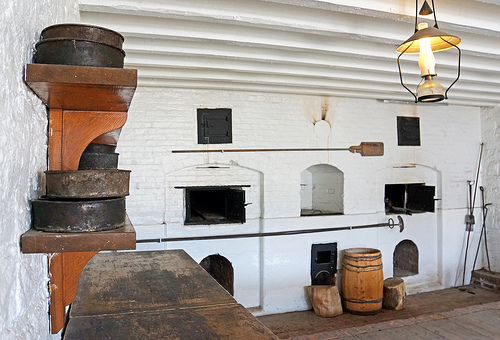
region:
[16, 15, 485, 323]
This is an old bakery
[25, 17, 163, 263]
Items for shaping bread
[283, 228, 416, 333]
A barrel on the floor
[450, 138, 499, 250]
Tools for moving bread in the oven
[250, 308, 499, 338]
A wooden floor here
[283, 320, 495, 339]
A matted rug on the floor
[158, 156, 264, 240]
The oven door is open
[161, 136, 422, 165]
A tool hung on the wall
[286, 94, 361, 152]
Burn marks on the wall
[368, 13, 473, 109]
An old lamp for seeing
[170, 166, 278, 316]
A small stove on wall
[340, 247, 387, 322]
A wooden barrel on the floor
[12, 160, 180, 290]
Metal on the shelf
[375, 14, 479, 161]
A light hanging from ceiling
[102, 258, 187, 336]
A wooden table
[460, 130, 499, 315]
Metal tools in the corner.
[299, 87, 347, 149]
A brown stain on the wall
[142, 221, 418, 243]
Metal rod hanging on the wall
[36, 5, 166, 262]
Two shelves with metal on them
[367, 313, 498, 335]
Wooden plank on the floor.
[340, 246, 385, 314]
The large wood barrel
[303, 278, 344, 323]
Stump to the left of the barrel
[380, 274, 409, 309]
Stump to the right of the barrel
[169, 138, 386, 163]
Large wood paddle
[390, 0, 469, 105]
Lantern hung from the ceiling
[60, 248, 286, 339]
Counter top on the left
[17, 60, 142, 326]
Wood shelves on the left wall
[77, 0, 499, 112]
Exposed wood beams on the roof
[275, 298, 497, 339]
The bricks that make up the floor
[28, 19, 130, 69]
the circle pans on the top shelf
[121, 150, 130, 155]
a brick on the wall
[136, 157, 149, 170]
a brick on the wall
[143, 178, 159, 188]
a brick on the wall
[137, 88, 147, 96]
a brick on the wall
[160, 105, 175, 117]
a brick on the wall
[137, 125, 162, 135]
a brick on the wall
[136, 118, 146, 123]
a brick on the wall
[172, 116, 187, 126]
a brick on the wall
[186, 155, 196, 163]
a brick on the wall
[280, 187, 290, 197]
a brick on the wall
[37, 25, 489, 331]
An antique kitchen.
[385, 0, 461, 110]
A lantern is hanging from the ceiling.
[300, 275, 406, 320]
Two blocks of wood.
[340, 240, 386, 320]
A wood barrel.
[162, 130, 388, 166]
A peel for the oven.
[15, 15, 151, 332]
The shelves are full of metal tins for baking.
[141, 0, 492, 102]
The ceiling's wood beams are visible.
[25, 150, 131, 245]
The metal tins are covered in rust.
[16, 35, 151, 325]
The shelves are made from wood.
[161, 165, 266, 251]
An oven.